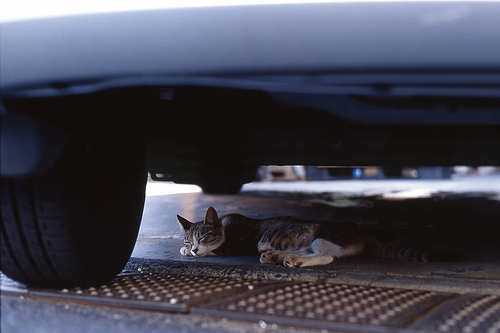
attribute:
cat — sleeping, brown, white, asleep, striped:
[177, 204, 434, 269]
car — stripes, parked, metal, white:
[2, 0, 500, 292]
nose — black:
[192, 246, 198, 255]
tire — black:
[1, 95, 147, 289]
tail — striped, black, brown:
[366, 233, 442, 264]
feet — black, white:
[259, 247, 336, 268]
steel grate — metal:
[2, 266, 499, 332]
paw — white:
[180, 246, 191, 257]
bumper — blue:
[1, 1, 499, 97]